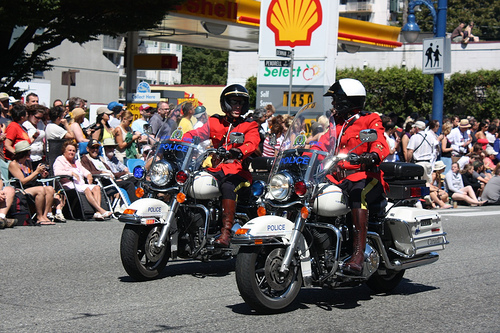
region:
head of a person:
[210, 73, 247, 118]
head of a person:
[315, 77, 371, 114]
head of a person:
[89, 97, 119, 124]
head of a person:
[61, 138, 80, 158]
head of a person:
[15, 140, 30, 156]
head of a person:
[2, 103, 33, 125]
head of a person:
[178, 90, 203, 115]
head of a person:
[397, 112, 415, 132]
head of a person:
[455, 110, 476, 129]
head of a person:
[446, 159, 463, 171]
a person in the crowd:
[13, 144, 52, 214]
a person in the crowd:
[50, 143, 113, 220]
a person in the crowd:
[3, 105, 30, 147]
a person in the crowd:
[46, 110, 71, 140]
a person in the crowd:
[28, 94, 43, 105]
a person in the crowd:
[144, 95, 166, 136]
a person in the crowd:
[182, 105, 195, 130]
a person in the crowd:
[447, 167, 474, 207]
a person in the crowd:
[429, 162, 444, 187]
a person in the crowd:
[410, 122, 435, 158]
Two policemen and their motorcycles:
[110, 76, 451, 313]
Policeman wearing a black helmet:
[173, 79, 271, 249]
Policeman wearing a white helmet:
[295, 73, 393, 276]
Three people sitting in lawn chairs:
[4, 136, 135, 228]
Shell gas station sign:
[255, 1, 342, 121]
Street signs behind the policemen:
[260, 45, 300, 73]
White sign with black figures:
[418, 34, 448, 79]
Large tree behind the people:
[0, 1, 171, 111]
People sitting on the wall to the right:
[445, 12, 484, 49]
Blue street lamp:
[400, 1, 455, 138]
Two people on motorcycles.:
[120, 82, 452, 312]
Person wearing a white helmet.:
[316, 76, 392, 273]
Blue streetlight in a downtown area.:
[401, 1, 458, 122]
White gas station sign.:
[256, 3, 338, 118]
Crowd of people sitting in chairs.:
[6, 90, 135, 221]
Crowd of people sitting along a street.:
[0, 73, 497, 332]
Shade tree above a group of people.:
[3, 0, 185, 220]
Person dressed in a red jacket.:
[175, 84, 262, 175]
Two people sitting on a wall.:
[449, 17, 498, 65]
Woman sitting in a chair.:
[45, 137, 112, 220]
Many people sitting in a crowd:
[3, 95, 127, 224]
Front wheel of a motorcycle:
[234, 233, 302, 310]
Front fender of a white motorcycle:
[119, 198, 178, 250]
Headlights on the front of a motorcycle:
[250, 173, 308, 202]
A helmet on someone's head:
[321, 78, 371, 117]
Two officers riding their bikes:
[121, 83, 447, 308]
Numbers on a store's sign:
[279, 89, 316, 109]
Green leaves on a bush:
[338, 68, 498, 120]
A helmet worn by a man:
[218, 80, 250, 118]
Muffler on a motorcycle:
[390, 253, 441, 269]